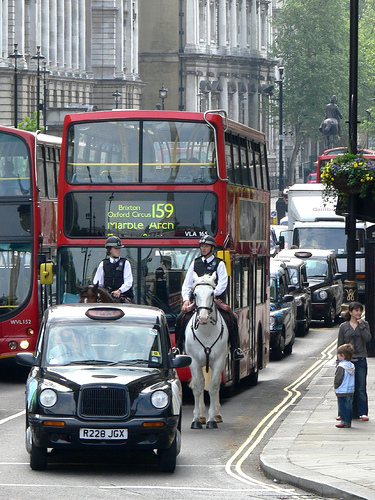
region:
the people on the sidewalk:
[329, 297, 373, 425]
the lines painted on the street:
[227, 390, 288, 483]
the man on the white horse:
[168, 233, 248, 433]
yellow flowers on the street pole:
[325, 154, 368, 199]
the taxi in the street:
[25, 293, 191, 476]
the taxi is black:
[37, 301, 189, 472]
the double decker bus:
[60, 107, 293, 381]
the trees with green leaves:
[284, 6, 360, 104]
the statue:
[304, 90, 352, 150]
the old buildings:
[19, 3, 253, 89]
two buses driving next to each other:
[3, 102, 279, 403]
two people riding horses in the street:
[62, 227, 246, 438]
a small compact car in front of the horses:
[12, 282, 226, 473]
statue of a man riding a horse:
[308, 89, 348, 164]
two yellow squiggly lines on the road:
[220, 337, 347, 498]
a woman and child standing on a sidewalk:
[334, 294, 371, 437]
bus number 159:
[134, 191, 186, 223]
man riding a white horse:
[173, 236, 253, 451]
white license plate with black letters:
[70, 424, 141, 442]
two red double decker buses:
[3, 104, 281, 422]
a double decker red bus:
[58, 109, 270, 392]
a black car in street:
[26, 303, 180, 472]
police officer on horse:
[174, 231, 247, 430]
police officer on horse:
[79, 233, 133, 301]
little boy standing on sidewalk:
[332, 341, 354, 428]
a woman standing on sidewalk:
[336, 302, 368, 421]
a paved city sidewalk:
[259, 364, 374, 496]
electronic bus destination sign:
[103, 200, 174, 236]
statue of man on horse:
[319, 95, 342, 149]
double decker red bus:
[0, 128, 63, 377]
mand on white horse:
[187, 231, 226, 433]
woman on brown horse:
[78, 237, 136, 302]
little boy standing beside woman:
[333, 301, 367, 430]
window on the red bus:
[3, 249, 31, 315]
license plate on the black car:
[78, 425, 129, 441]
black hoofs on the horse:
[190, 415, 217, 428]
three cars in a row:
[270, 247, 335, 347]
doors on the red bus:
[233, 256, 267, 374]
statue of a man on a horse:
[310, 87, 344, 142]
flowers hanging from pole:
[322, 151, 373, 188]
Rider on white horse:
[174, 228, 246, 438]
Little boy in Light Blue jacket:
[327, 337, 365, 437]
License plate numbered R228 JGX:
[69, 416, 144, 449]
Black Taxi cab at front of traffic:
[21, 247, 203, 472]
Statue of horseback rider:
[306, 87, 355, 155]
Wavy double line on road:
[221, 277, 352, 498]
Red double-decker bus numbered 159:
[33, 86, 290, 389]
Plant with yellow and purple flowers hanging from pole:
[312, 138, 372, 200]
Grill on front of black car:
[67, 380, 148, 424]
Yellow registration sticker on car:
[145, 342, 167, 368]